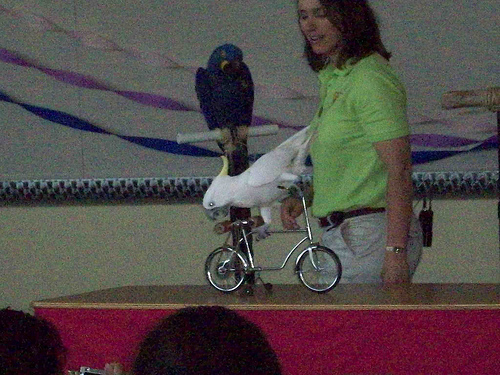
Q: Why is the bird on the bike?
A: Show.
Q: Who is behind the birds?
A: Trainer.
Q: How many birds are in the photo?
A: Two.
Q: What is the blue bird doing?
A: Sitting.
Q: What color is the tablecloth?
A: Red.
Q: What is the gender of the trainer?
A: Female.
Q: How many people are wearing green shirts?
A: One.